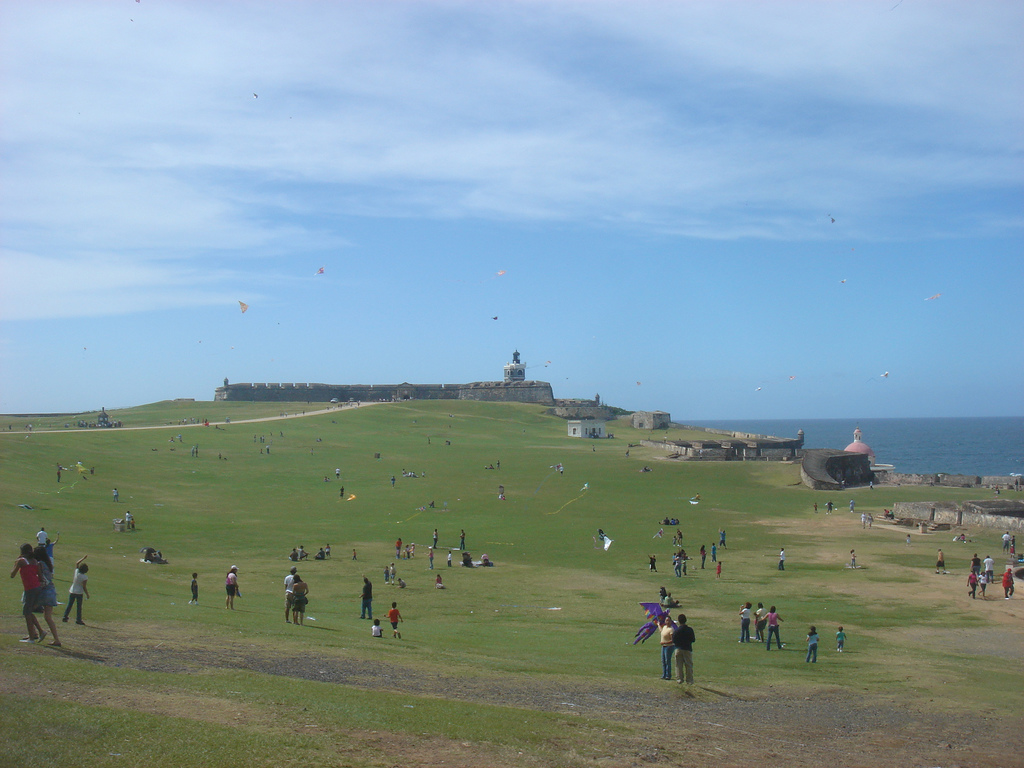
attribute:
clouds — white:
[358, 99, 417, 137]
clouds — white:
[667, 18, 735, 98]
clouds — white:
[854, 179, 908, 237]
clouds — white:
[724, 365, 767, 408]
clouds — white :
[794, 247, 881, 302]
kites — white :
[422, 239, 509, 294]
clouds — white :
[428, 238, 509, 295]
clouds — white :
[525, 83, 628, 183]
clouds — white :
[95, 198, 220, 291]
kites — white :
[45, 35, 169, 109]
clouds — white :
[45, 35, 169, 109]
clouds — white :
[336, 77, 455, 188]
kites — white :
[336, 77, 455, 188]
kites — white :
[634, 46, 721, 154]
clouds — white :
[634, 46, 721, 154]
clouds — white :
[768, 248, 864, 363]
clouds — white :
[137, 128, 201, 192]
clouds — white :
[277, 70, 331, 113]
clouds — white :
[330, 216, 473, 321]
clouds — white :
[494, 147, 605, 255]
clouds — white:
[111, 141, 276, 297]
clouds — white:
[197, 79, 640, 269]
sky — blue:
[609, 282, 966, 384]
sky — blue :
[400, 70, 856, 341]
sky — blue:
[0, 8, 1018, 426]